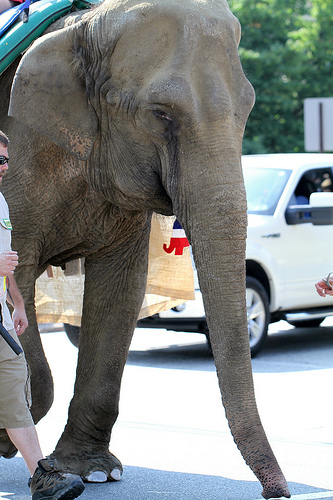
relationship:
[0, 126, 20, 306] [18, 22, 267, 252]
man beside elephant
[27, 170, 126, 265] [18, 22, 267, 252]
wrinkles on elephant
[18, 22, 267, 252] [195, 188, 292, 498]
elephant has trunk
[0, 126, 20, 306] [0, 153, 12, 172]
man wearing sunglasses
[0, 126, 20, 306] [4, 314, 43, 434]
man wearing shorts